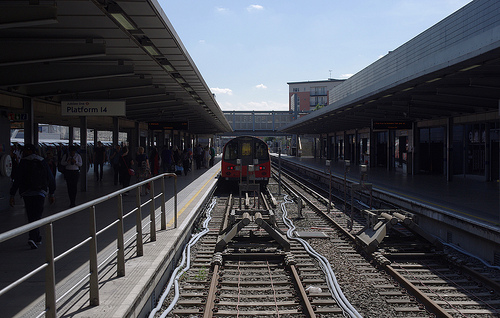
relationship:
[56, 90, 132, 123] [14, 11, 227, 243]
sign at station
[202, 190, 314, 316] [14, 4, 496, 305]
tracks at station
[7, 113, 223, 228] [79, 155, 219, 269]
people on walkway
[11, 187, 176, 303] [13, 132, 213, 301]
railing on walkway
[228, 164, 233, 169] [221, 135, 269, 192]
light on train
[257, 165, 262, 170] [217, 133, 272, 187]
red light on train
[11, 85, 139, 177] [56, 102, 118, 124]
number on sign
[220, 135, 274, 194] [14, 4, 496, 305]
train in station